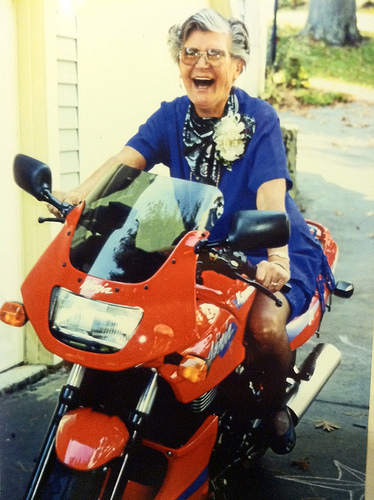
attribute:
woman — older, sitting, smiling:
[45, 9, 333, 455]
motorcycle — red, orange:
[1, 153, 344, 498]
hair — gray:
[167, 7, 250, 66]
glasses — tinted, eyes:
[177, 46, 233, 62]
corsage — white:
[212, 107, 248, 164]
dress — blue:
[125, 87, 336, 337]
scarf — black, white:
[182, 93, 257, 192]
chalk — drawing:
[275, 456, 362, 500]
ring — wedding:
[269, 279, 279, 287]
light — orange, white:
[49, 283, 144, 351]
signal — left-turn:
[179, 357, 208, 385]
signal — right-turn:
[1, 301, 27, 327]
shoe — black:
[255, 389, 297, 454]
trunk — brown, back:
[295, 1, 370, 47]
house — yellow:
[2, 2, 274, 302]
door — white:
[77, 3, 209, 185]